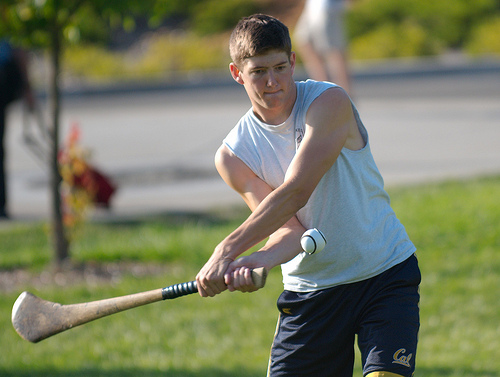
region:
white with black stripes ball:
[301, 222, 331, 258]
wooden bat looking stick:
[6, 253, 294, 355]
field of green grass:
[413, 193, 498, 358]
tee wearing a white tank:
[187, 53, 427, 285]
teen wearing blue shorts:
[263, 275, 433, 367]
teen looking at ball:
[197, 20, 384, 301]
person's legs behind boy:
[286, 4, 366, 90]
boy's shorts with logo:
[392, 346, 417, 371]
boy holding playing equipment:
[14, 14, 461, 369]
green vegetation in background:
[76, 42, 167, 67]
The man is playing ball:
[25, 9, 458, 367]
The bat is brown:
[7, 274, 286, 343]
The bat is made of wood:
[0, 273, 220, 340]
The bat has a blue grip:
[138, 265, 213, 307]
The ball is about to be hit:
[276, 213, 351, 271]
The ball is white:
[281, 219, 346, 258]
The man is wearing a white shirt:
[186, 69, 433, 294]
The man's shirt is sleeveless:
[192, 121, 267, 198]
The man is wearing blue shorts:
[264, 250, 421, 375]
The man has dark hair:
[194, 8, 316, 66]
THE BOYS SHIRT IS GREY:
[187, 70, 425, 291]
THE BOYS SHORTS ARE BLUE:
[237, 242, 423, 373]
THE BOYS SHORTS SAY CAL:
[386, 341, 417, 373]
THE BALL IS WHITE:
[293, 217, 334, 267]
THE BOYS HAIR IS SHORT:
[218, 7, 303, 78]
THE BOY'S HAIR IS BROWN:
[217, 2, 314, 74]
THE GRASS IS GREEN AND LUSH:
[0, 172, 498, 365]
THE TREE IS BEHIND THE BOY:
[15, 2, 100, 268]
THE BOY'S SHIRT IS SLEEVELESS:
[195, 72, 431, 297]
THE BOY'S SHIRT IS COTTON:
[208, 69, 429, 294]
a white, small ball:
[288, 225, 344, 271]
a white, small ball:
[265, 187, 331, 271]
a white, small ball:
[270, 212, 346, 289]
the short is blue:
[226, 263, 414, 371]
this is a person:
[197, 6, 442, 374]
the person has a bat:
[8, 220, 322, 355]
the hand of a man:
[178, 80, 343, 313]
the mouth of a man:
[262, 85, 288, 99]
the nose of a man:
[264, 76, 279, 90]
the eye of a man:
[271, 57, 293, 86]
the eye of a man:
[250, 65, 270, 81]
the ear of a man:
[290, 51, 305, 68]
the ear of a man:
[220, 60, 245, 85]